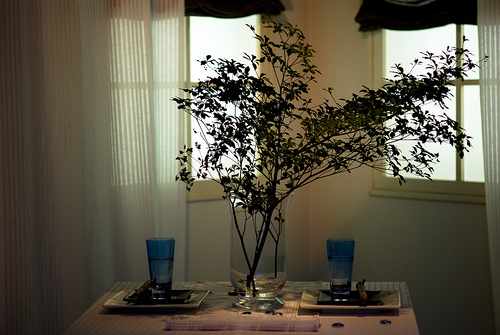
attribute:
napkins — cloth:
[180, 300, 347, 332]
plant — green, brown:
[163, 7, 489, 208]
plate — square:
[103, 286, 209, 307]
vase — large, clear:
[223, 190, 290, 315]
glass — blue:
[323, 234, 357, 304]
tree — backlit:
[164, 30, 499, 292]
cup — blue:
[141, 235, 181, 310]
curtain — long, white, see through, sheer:
[1, 0, 188, 332]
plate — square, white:
[112, 282, 223, 316]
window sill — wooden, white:
[370, 172, 492, 206]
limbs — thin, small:
[148, 20, 452, 218]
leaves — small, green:
[322, 94, 373, 126]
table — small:
[56, 275, 438, 333]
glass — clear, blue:
[312, 222, 363, 305]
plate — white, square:
[298, 283, 408, 311]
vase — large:
[313, 232, 363, 314]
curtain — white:
[4, 1, 191, 299]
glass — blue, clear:
[144, 237, 175, 289]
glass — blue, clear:
[326, 237, 356, 295]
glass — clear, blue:
[148, 236, 175, 291]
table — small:
[107, 251, 327, 332]